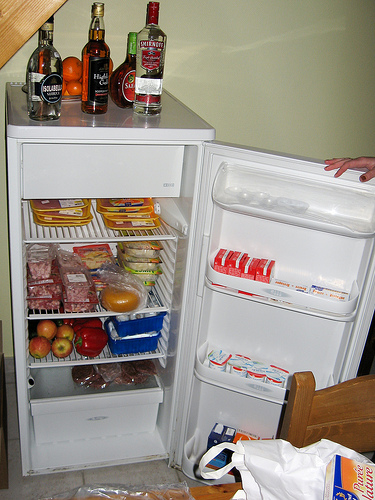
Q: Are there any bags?
A: Yes, there is a bag.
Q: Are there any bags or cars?
A: Yes, there is a bag.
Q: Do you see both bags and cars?
A: No, there is a bag but no cars.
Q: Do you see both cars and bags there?
A: No, there is a bag but no cars.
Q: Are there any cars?
A: No, there are no cars.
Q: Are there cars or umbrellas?
A: No, there are no cars or umbrellas.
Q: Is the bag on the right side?
A: Yes, the bag is on the right of the image.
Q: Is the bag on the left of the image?
A: No, the bag is on the right of the image.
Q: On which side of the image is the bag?
A: The bag is on the right of the image.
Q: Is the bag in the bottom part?
A: Yes, the bag is in the bottom of the image.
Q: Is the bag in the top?
A: No, the bag is in the bottom of the image.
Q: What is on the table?
A: The bag is on the table.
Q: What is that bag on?
A: The bag is on the table.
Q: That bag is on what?
A: The bag is on the table.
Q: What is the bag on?
A: The bag is on the table.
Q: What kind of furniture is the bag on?
A: The bag is on the table.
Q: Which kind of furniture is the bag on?
A: The bag is on the table.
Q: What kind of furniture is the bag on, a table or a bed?
A: The bag is on a table.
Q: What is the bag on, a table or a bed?
A: The bag is on a table.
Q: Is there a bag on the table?
A: Yes, there is a bag on the table.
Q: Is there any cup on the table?
A: No, there is a bag on the table.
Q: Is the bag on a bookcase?
A: No, the bag is on the table.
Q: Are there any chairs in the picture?
A: Yes, there is a chair.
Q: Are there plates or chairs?
A: Yes, there is a chair.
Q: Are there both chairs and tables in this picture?
A: Yes, there are both a chair and a table.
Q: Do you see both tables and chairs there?
A: Yes, there are both a chair and a table.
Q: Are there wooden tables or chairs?
A: Yes, there is a wood chair.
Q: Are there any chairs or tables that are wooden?
A: Yes, the chair is wooden.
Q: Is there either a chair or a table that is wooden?
A: Yes, the chair is wooden.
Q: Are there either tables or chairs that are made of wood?
A: Yes, the chair is made of wood.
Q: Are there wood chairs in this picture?
A: Yes, there is a wood chair.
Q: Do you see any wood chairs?
A: Yes, there is a wood chair.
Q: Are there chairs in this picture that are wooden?
A: Yes, there is a chair that is wooden.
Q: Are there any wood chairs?
A: Yes, there is a chair that is made of wood.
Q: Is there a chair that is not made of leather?
A: Yes, there is a chair that is made of wood.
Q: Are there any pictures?
A: No, there are no pictures.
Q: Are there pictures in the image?
A: No, there are no pictures.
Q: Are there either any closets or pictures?
A: No, there are no pictures or closets.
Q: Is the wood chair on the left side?
A: No, the chair is on the right of the image.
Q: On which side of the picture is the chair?
A: The chair is on the right of the image.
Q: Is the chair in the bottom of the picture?
A: Yes, the chair is in the bottom of the image.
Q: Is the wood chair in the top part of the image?
A: No, the chair is in the bottom of the image.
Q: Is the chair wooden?
A: Yes, the chair is wooden.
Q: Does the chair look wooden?
A: Yes, the chair is wooden.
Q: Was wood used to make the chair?
A: Yes, the chair is made of wood.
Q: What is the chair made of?
A: The chair is made of wood.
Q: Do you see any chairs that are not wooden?
A: No, there is a chair but it is wooden.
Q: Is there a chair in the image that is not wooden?
A: No, there is a chair but it is wooden.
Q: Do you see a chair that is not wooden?
A: No, there is a chair but it is wooden.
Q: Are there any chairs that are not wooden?
A: No, there is a chair but it is wooden.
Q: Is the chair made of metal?
A: No, the chair is made of wood.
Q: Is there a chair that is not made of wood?
A: No, there is a chair but it is made of wood.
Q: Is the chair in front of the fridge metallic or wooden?
A: The chair is wooden.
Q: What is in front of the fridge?
A: The chair is in front of the fridge.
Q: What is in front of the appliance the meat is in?
A: The chair is in front of the fridge.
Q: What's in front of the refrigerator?
A: The chair is in front of the fridge.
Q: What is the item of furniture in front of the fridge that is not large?
A: The piece of furniture is a chair.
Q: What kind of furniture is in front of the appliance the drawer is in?
A: The piece of furniture is a chair.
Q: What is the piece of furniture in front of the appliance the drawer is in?
A: The piece of furniture is a chair.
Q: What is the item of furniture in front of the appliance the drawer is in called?
A: The piece of furniture is a chair.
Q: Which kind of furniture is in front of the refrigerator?
A: The piece of furniture is a chair.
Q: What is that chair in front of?
A: The chair is in front of the refrigerator.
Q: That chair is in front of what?
A: The chair is in front of the refrigerator.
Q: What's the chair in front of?
A: The chair is in front of the refrigerator.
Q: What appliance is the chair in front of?
A: The chair is in front of the refrigerator.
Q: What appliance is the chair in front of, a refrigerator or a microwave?
A: The chair is in front of a refrigerator.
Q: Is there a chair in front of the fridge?
A: Yes, there is a chair in front of the fridge.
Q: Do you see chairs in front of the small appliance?
A: Yes, there is a chair in front of the fridge.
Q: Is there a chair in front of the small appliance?
A: Yes, there is a chair in front of the fridge.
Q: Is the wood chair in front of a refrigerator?
A: Yes, the chair is in front of a refrigerator.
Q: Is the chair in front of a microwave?
A: No, the chair is in front of a refrigerator.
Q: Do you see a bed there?
A: No, there are no beds.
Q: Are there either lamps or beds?
A: No, there are no beds or lamps.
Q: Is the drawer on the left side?
A: Yes, the drawer is on the left of the image.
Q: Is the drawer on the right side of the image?
A: No, the drawer is on the left of the image.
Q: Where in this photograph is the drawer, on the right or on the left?
A: The drawer is on the left of the image.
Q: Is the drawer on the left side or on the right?
A: The drawer is on the left of the image.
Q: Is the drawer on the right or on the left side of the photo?
A: The drawer is on the left of the image.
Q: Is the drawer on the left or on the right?
A: The drawer is on the left of the image.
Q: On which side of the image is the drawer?
A: The drawer is on the left of the image.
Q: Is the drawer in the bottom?
A: Yes, the drawer is in the bottom of the image.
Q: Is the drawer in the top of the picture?
A: No, the drawer is in the bottom of the image.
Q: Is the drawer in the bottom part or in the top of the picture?
A: The drawer is in the bottom of the image.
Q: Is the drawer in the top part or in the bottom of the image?
A: The drawer is in the bottom of the image.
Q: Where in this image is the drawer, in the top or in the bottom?
A: The drawer is in the bottom of the image.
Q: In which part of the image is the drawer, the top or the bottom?
A: The drawer is in the bottom of the image.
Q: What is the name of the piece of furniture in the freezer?
A: The piece of furniture is a drawer.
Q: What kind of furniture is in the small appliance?
A: The piece of furniture is a drawer.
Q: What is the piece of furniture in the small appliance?
A: The piece of furniture is a drawer.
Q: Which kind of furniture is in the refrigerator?
A: The piece of furniture is a drawer.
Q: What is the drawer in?
A: The drawer is in the refrigerator.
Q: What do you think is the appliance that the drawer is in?
A: The appliance is a refrigerator.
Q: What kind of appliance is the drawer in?
A: The drawer is in the freezer.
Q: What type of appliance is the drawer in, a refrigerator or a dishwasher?
A: The drawer is in a refrigerator.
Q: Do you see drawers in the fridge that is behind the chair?
A: Yes, there is a drawer in the freezer.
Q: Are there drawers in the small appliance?
A: Yes, there is a drawer in the freezer.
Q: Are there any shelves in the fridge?
A: No, there is a drawer in the fridge.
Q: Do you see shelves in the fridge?
A: No, there is a drawer in the fridge.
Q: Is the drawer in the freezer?
A: Yes, the drawer is in the freezer.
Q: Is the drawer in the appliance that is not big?
A: Yes, the drawer is in the freezer.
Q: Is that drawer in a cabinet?
A: No, the drawer is in the freezer.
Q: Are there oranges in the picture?
A: Yes, there are oranges.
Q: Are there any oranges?
A: Yes, there are oranges.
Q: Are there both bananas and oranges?
A: No, there are oranges but no bananas.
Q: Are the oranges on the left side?
A: Yes, the oranges are on the left of the image.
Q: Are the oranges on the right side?
A: No, the oranges are on the left of the image.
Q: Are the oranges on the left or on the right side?
A: The oranges are on the left of the image.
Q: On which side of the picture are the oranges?
A: The oranges are on the left of the image.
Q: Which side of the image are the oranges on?
A: The oranges are on the left of the image.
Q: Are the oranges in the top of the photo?
A: Yes, the oranges are in the top of the image.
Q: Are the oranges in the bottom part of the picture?
A: No, the oranges are in the top of the image.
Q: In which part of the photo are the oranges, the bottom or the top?
A: The oranges are in the top of the image.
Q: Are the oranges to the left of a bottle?
A: Yes, the oranges are to the left of a bottle.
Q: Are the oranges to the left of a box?
A: No, the oranges are to the left of a bottle.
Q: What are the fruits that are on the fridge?
A: The fruits are oranges.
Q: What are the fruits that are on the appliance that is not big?
A: The fruits are oranges.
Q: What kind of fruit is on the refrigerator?
A: The fruits are oranges.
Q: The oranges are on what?
A: The oranges are on the refrigerator.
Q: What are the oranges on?
A: The oranges are on the refrigerator.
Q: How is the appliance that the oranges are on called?
A: The appliance is a refrigerator.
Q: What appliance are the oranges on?
A: The oranges are on the refrigerator.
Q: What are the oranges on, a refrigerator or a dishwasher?
A: The oranges are on a refrigerator.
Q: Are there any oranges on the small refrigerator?
A: Yes, there are oranges on the refrigerator.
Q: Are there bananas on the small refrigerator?
A: No, there are oranges on the refrigerator.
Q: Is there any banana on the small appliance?
A: No, there are oranges on the refrigerator.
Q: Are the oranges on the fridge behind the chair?
A: Yes, the oranges are on the freezer.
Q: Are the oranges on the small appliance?
A: Yes, the oranges are on the freezer.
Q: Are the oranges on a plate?
A: No, the oranges are on the freezer.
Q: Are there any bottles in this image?
A: Yes, there is a bottle.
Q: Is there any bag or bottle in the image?
A: Yes, there is a bottle.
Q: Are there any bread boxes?
A: No, there are no bread boxes.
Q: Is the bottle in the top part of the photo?
A: Yes, the bottle is in the top of the image.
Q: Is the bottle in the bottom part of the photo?
A: No, the bottle is in the top of the image.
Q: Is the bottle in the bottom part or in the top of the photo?
A: The bottle is in the top of the image.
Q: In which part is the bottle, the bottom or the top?
A: The bottle is in the top of the image.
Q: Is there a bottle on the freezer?
A: Yes, there is a bottle on the freezer.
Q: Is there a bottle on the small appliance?
A: Yes, there is a bottle on the freezer.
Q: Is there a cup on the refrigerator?
A: No, there is a bottle on the refrigerator.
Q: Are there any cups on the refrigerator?
A: No, there is a bottle on the refrigerator.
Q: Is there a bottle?
A: Yes, there is a bottle.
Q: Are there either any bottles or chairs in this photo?
A: Yes, there is a bottle.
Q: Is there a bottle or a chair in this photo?
A: Yes, there is a bottle.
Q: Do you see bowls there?
A: No, there are no bowls.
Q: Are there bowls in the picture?
A: No, there are no bowls.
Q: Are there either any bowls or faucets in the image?
A: No, there are no bowls or faucets.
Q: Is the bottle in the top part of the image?
A: Yes, the bottle is in the top of the image.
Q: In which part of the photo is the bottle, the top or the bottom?
A: The bottle is in the top of the image.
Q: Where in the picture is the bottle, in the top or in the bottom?
A: The bottle is in the top of the image.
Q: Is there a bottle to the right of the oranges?
A: Yes, there is a bottle to the right of the oranges.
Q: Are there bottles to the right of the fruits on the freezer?
A: Yes, there is a bottle to the right of the oranges.